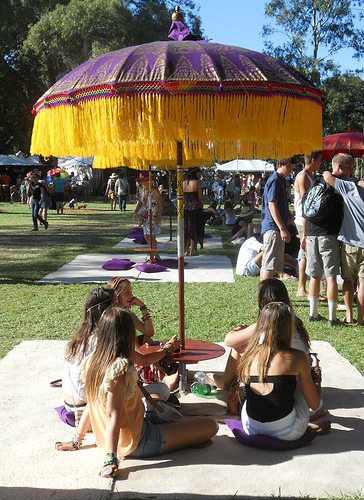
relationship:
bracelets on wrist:
[62, 430, 92, 447] [48, 431, 94, 446]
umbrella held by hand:
[25, 44, 269, 202] [162, 321, 210, 367]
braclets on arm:
[136, 299, 153, 327] [132, 301, 150, 330]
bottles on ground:
[183, 365, 217, 399] [195, 389, 218, 409]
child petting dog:
[60, 191, 77, 214] [75, 197, 89, 215]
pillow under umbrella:
[134, 264, 168, 273] [74, 142, 159, 167]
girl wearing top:
[235, 301, 322, 442] [228, 359, 313, 425]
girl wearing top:
[55, 303, 219, 478] [86, 369, 143, 453]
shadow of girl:
[111, 421, 362, 478] [55, 303, 219, 478]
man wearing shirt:
[259, 157, 293, 284] [260, 170, 284, 234]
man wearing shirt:
[300, 152, 353, 326] [305, 171, 352, 235]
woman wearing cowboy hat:
[134, 171, 164, 262] [135, 171, 155, 182]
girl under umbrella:
[52, 308, 218, 475] [28, 7, 321, 166]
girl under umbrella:
[74, 287, 125, 402] [28, 7, 321, 166]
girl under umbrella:
[234, 302, 322, 443] [28, 7, 321, 166]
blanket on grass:
[3, 339, 363, 497] [3, 198, 354, 494]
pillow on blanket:
[102, 257, 134, 270] [34, 253, 231, 283]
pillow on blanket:
[135, 263, 166, 272] [34, 253, 231, 283]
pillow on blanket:
[155, 259, 185, 269] [34, 253, 231, 283]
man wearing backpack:
[300, 152, 353, 326] [303, 178, 349, 233]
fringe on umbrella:
[32, 91, 321, 171] [28, 7, 321, 166]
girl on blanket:
[55, 303, 219, 478] [3, 339, 363, 497]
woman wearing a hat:
[134, 171, 164, 262] [133, 168, 153, 181]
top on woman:
[226, 353, 323, 429] [232, 311, 316, 449]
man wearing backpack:
[300, 149, 356, 326] [298, 179, 345, 230]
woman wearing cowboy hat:
[131, 168, 165, 265] [134, 168, 150, 183]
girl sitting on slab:
[55, 303, 219, 478] [1, 334, 357, 498]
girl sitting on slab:
[62, 287, 170, 412] [1, 334, 357, 498]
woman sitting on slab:
[103, 275, 155, 338] [1, 334, 357, 498]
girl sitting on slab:
[235, 301, 322, 442] [1, 334, 357, 498]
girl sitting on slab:
[205, 277, 312, 408] [1, 334, 357, 498]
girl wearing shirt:
[235, 301, 322, 442] [243, 372, 300, 424]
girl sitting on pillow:
[235, 301, 322, 442] [219, 416, 321, 453]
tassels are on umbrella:
[28, 87, 329, 171] [28, 7, 321, 166]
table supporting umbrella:
[134, 334, 227, 364] [28, 7, 321, 166]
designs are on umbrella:
[165, 51, 205, 82] [27, 2, 328, 112]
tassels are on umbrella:
[28, 87, 329, 171] [27, 2, 328, 112]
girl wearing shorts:
[52, 308, 218, 475] [123, 412, 165, 459]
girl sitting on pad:
[52, 308, 218, 475] [3, 335, 363, 497]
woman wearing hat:
[131, 168, 165, 265] [132, 168, 154, 183]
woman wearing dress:
[131, 168, 165, 265] [135, 184, 162, 238]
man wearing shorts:
[300, 149, 356, 326] [298, 232, 341, 280]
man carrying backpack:
[300, 149, 356, 326] [298, 177, 342, 229]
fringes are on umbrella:
[23, 91, 326, 174] [27, 4, 329, 179]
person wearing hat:
[103, 170, 121, 209] [106, 171, 120, 181]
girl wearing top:
[233, 299, 332, 442] [240, 372, 297, 424]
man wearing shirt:
[256, 157, 293, 284] [258, 169, 290, 236]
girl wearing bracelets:
[52, 308, 218, 475] [67, 429, 90, 446]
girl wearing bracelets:
[52, 308, 218, 475] [100, 450, 118, 466]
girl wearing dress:
[179, 165, 206, 257] [183, 189, 202, 244]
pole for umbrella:
[168, 162, 197, 384] [25, 14, 341, 415]